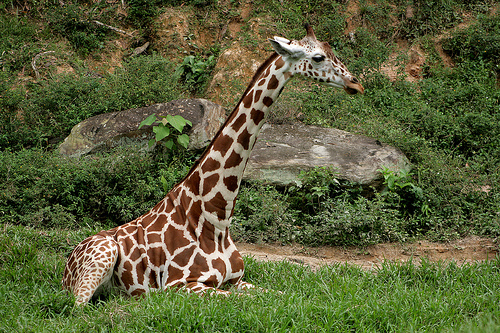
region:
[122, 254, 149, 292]
Brown spots on an animal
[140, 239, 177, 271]
Brown spots on an animal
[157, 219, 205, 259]
Brown spots on an animal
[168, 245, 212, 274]
Brown spots on an animal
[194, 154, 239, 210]
Brown spots on an animal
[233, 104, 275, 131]
Brown spots on an animal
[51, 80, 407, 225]
Large rocks in the grass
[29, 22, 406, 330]
Giraffe sitting in a field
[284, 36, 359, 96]
Brown spots on an animal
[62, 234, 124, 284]
Brown spots on an animal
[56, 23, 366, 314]
a giraffe that is laying down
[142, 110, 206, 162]
a large leaf plant growing out of a rock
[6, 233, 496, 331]
green grass in a field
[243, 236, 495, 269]
exposed dirt in a field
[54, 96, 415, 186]
a large, barren rock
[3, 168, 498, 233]
bushes growing below a rock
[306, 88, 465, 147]
bushes growing above a rock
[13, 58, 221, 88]
bushes growing above a rock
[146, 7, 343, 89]
barren ground above rock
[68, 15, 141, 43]
a stick near some bushes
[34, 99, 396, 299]
A giraffe is sitting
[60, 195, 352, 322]
A brown and white giraffe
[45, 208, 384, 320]
The giraffe is on the grass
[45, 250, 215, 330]
The grass is green and tall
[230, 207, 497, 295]
Brown dirt is on the ground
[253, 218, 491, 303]
The brown dirt is next to the grass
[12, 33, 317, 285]
The giraffe has two ears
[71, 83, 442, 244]
The tree is behind the giraffe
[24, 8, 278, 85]
Trees are behind the giraffe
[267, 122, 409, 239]
A brown rock is behind the giraffe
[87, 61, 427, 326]
This is a giraffe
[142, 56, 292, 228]
This is a long neck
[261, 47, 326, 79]
This is an ear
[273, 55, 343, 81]
This is an eye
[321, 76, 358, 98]
This is a mouth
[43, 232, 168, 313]
This is a leg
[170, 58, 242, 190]
The giraffe is brown and white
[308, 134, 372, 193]
This is a large rock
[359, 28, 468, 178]
This is a large bush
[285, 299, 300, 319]
The grass is short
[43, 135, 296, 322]
The giraffe is sitting down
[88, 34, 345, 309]
The giraffe is in the grass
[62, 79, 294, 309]
The giraffe is brown and white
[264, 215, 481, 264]
Dirt is next to the grass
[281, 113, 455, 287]
The rock is next to the grass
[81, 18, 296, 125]
The rocks are next to the grass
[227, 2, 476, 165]
The giraffe has a long neck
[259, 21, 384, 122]
Two ears are on the giraffe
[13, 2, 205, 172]
Grass covers the rocks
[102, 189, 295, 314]
The giraffe has big brown spots